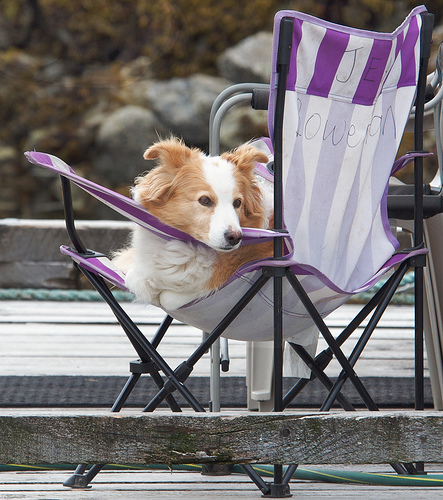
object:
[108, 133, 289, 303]
dog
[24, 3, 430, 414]
chair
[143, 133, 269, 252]
head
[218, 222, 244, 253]
mouth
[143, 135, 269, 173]
ears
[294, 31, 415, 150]
writing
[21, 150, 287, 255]
arm rest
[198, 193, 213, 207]
eye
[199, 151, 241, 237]
white stripe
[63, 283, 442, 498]
metal poles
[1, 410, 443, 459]
post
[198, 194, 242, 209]
brown eyes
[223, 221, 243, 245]
nose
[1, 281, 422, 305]
rope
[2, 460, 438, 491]
hose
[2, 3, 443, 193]
trees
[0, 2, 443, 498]
photo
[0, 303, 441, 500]
deck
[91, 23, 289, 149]
rocks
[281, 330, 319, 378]
tag